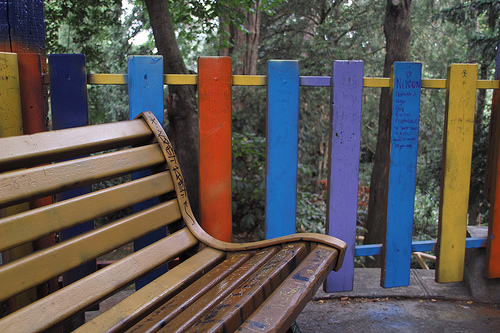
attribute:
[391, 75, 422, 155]
writing — black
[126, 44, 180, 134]
post — blue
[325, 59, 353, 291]
post — purple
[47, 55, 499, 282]
fence — colorful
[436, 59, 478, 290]
post — yellow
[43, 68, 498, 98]
beam — yellow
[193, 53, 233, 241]
post — orange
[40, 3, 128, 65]
leaves — different types 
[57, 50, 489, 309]
fence — colorful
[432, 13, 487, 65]
tree — dark, green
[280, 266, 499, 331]
walk — concrete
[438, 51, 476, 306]
post — yellow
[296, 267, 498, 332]
patio — concrete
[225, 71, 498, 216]
fence — orange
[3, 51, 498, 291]
fence — blue, yellow, purple, red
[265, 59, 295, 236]
post — blue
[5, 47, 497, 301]
picket fence — Multi-colored wooden picket 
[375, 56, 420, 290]
post — blue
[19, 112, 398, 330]
bench — brown 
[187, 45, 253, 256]
post — red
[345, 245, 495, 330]
cement — grey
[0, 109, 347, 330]
bench — wooden  , stained a  , light color , brown, empty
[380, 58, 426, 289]
fence post — blue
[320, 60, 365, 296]
fence post — blue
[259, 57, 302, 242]
fence post — blue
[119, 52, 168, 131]
fence post — blue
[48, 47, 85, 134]
fence post — blue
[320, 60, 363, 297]
post — purple